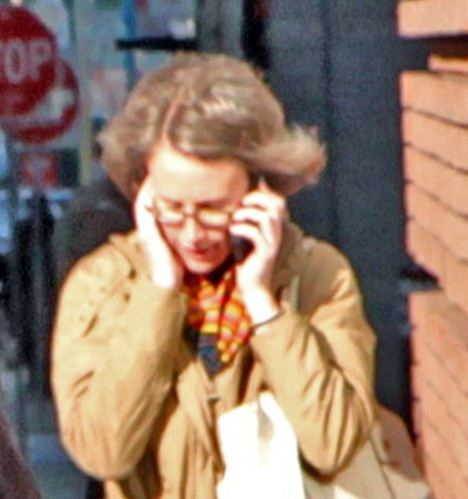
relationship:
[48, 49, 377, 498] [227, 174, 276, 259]
woman talking on cell phone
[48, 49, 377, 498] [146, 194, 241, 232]
woman wearing glasses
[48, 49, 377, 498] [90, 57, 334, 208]
woman has hair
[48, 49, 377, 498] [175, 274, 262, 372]
woman wearing scarf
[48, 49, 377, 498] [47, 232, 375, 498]
woman wearing jacket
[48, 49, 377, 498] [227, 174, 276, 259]
woman holding cell phone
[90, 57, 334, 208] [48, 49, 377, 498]
head of woman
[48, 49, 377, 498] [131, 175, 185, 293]
woman holding hand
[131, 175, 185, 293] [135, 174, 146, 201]
hand to ear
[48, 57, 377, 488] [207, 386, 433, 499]
woman holding bag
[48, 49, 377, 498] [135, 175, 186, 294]
woman holds hand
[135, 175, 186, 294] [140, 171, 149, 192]
hand to ear